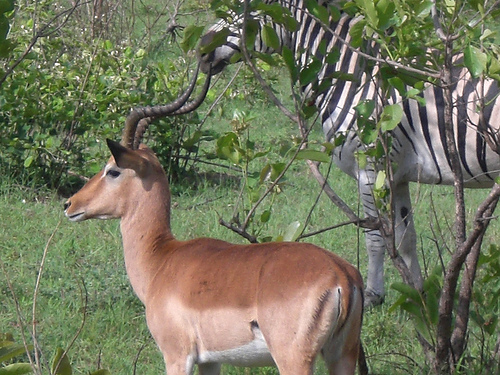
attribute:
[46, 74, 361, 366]
gazelle — brown, standing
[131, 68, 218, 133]
horns — black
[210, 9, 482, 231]
zebra — striped, black, whtie, standing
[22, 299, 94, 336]
grass — green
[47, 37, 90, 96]
leaves — green